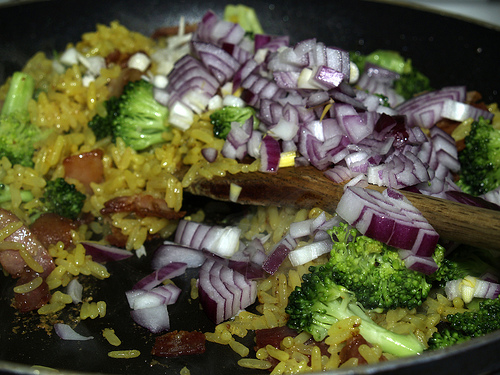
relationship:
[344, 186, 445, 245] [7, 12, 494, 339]
onion on pan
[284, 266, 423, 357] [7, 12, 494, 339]
broccoli in pan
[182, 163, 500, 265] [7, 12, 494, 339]
spoon in pan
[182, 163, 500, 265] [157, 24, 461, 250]
spoon by onion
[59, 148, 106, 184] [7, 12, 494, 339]
bacon in pan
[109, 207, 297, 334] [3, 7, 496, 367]
onion in pan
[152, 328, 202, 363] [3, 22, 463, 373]
bacon stirred into rice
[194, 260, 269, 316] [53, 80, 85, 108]
onion beside rice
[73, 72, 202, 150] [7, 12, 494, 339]
broccoli in pan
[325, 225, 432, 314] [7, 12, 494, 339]
broccoli in pan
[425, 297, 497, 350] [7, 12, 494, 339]
broccoli in pan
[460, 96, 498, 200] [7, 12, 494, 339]
broccoli in pan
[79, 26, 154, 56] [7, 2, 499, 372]
rice in wok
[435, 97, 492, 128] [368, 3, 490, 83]
onion in wok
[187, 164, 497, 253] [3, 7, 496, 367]
spoon in a pan